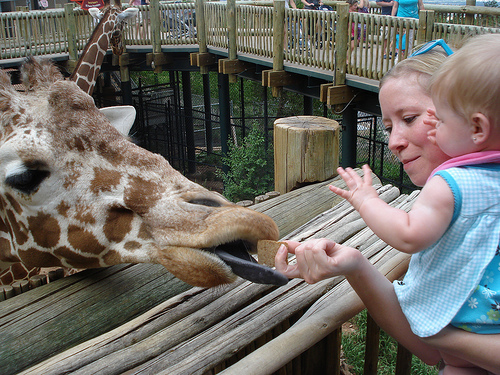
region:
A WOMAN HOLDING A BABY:
[305, 20, 497, 370]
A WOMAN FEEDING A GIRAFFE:
[249, 15, 498, 369]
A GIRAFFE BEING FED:
[6, 61, 367, 310]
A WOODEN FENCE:
[192, 3, 386, 93]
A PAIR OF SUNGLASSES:
[399, 33, 457, 65]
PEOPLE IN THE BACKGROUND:
[271, 3, 435, 60]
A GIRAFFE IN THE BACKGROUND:
[66, 3, 151, 105]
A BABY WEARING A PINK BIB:
[419, 30, 498, 256]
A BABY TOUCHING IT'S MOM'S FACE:
[320, 30, 496, 260]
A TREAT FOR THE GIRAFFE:
[7, 117, 312, 281]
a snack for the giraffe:
[256, 239, 287, 269]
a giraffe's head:
[1, 54, 287, 307]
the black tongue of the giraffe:
[216, 240, 286, 287]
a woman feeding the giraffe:
[273, 38, 498, 373]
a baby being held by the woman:
[327, 30, 498, 333]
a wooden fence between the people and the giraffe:
[1, 114, 421, 374]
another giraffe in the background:
[67, 2, 139, 98]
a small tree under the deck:
[218, 120, 271, 205]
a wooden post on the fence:
[273, 115, 340, 194]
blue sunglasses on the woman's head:
[406, 37, 451, 57]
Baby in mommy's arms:
[371, 20, 497, 297]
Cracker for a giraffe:
[250, 231, 295, 273]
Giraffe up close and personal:
[0, 77, 285, 272]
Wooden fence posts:
[230, 5, 376, 80]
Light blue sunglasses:
[390, 30, 460, 70]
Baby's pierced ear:
[467, 110, 488, 145]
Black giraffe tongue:
[220, 250, 285, 310]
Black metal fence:
[150, 95, 267, 157]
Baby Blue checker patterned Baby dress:
[395, 166, 495, 326]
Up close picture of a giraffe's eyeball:
[2, 161, 52, 196]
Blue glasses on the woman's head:
[361, 22, 468, 177]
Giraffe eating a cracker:
[26, 78, 306, 314]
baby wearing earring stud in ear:
[433, 71, 498, 174]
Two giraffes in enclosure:
[35, 16, 224, 323]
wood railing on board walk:
[189, 1, 459, 82]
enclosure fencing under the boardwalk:
[153, 95, 267, 175]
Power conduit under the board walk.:
[330, 38, 369, 126]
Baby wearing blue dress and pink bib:
[426, 28, 498, 340]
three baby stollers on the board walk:
[156, 6, 340, 51]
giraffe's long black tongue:
[203, 215, 301, 316]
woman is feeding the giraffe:
[23, 55, 495, 363]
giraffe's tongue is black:
[186, 242, 299, 303]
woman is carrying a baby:
[338, 27, 498, 324]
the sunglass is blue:
[363, 15, 463, 133]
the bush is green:
[207, 127, 284, 196]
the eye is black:
[0, 49, 129, 279]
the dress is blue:
[411, 157, 495, 342]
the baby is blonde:
[433, 40, 496, 135]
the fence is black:
[147, 80, 213, 170]